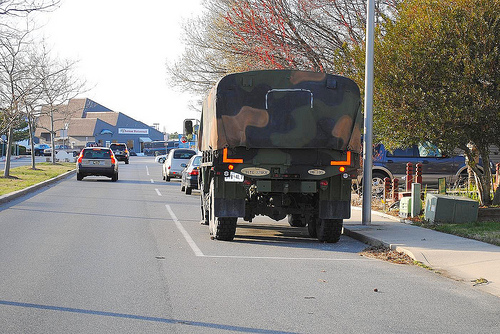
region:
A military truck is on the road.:
[187, 60, 363, 250]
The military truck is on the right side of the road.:
[170, 65, 360, 250]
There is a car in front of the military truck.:
[176, 150, 211, 192]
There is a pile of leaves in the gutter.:
[360, 240, 410, 270]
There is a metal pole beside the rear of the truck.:
[355, 0, 382, 225]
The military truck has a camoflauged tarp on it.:
[191, 69, 361, 164]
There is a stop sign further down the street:
[172, 130, 191, 149]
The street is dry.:
[0, 139, 494, 332]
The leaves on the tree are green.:
[351, 0, 499, 210]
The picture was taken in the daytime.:
[2, 4, 497, 332]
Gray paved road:
[60, 201, 235, 305]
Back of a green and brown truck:
[182, 74, 376, 247]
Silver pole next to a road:
[348, 26, 420, 246]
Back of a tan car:
[73, 141, 111, 178]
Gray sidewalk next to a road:
[348, 203, 491, 298]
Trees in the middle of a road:
[1, 49, 88, 176]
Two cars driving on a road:
[70, 132, 142, 204]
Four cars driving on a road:
[82, 131, 226, 205]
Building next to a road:
[28, 99, 183, 171]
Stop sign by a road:
[171, 129, 204, 146]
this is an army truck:
[201, 72, 351, 234]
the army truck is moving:
[204, 73, 363, 243]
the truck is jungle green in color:
[211, 76, 360, 233]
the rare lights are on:
[215, 165, 347, 173]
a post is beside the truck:
[362, 0, 377, 218]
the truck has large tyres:
[221, 221, 341, 240]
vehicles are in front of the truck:
[170, 145, 196, 192]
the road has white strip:
[167, 204, 198, 268]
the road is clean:
[25, 207, 135, 321]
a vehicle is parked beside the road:
[385, 146, 457, 185]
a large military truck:
[168, 55, 376, 258]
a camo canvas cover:
[187, 55, 369, 162]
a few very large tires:
[186, 170, 246, 244]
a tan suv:
[67, 135, 132, 187]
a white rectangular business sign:
[106, 120, 165, 146]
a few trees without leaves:
[1, 1, 79, 199]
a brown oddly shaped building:
[31, 85, 172, 165]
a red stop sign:
[174, 132, 198, 151]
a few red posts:
[376, 153, 437, 210]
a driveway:
[385, 207, 499, 323]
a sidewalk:
[409, 222, 451, 271]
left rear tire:
[209, 203, 239, 243]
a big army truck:
[218, 71, 348, 243]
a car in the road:
[73, 145, 128, 184]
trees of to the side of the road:
[0, 79, 28, 176]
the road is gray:
[96, 199, 138, 292]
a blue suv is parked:
[386, 129, 456, 184]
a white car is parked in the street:
[156, 149, 186, 173]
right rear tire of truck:
[318, 217, 349, 242]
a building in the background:
[86, 96, 147, 141]